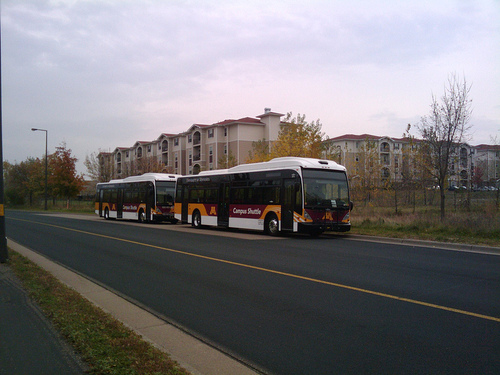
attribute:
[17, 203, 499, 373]
line — yellow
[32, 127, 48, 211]
street lamp — tall, grey, steel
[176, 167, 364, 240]
bus — metro, waiting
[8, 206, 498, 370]
road — asphalt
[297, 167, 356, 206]
windshield — wind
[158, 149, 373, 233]
bus — long, white, passenger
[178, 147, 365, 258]
bus — metro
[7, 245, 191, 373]
grass — patch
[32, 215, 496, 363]
stripe — yellow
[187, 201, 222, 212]
paint — yellow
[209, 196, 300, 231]
banner — purple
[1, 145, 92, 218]
trees — line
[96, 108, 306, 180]
building — tan, beige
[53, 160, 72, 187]
leaves — changing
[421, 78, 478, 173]
limbs — bare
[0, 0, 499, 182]
sky — cloudy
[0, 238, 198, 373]
grass — green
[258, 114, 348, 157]
leaves — golden